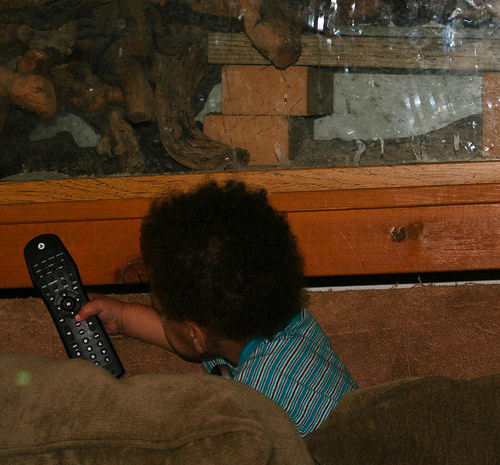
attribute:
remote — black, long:
[12, 230, 139, 382]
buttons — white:
[33, 257, 109, 373]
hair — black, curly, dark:
[136, 168, 316, 340]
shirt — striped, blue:
[217, 294, 367, 436]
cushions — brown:
[4, 345, 332, 464]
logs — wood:
[1, 6, 308, 167]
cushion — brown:
[5, 341, 331, 464]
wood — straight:
[203, 11, 498, 93]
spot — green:
[0, 364, 45, 396]